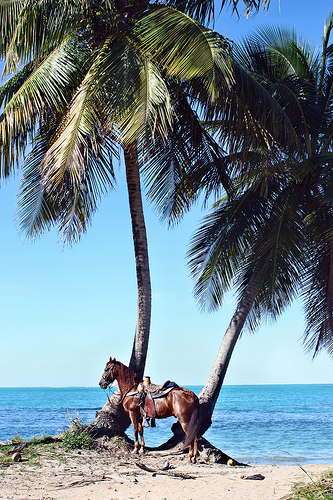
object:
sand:
[95, 443, 165, 492]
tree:
[0, 0, 280, 436]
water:
[243, 382, 302, 448]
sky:
[0, 184, 333, 388]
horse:
[98, 354, 203, 465]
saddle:
[137, 376, 175, 398]